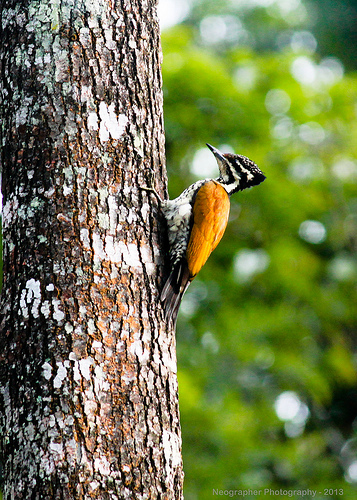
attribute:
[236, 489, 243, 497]
letter — style, print, transparent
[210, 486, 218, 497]
letter — transparent, print, style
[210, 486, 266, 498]
letter — white, print, style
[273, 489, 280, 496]
letter — style, print, transparent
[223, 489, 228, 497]
letter — white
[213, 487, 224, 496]
white print — letter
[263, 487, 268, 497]
letter — print, transparent, style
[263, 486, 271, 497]
letter — style, print, transparent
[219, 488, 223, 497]
letter — transparent, print, style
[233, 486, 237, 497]
letter — transparent, print, style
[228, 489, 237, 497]
letter — white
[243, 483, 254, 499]
letter — transparent, style, print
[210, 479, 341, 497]
letter — style, print, white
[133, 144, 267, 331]
bird — striped